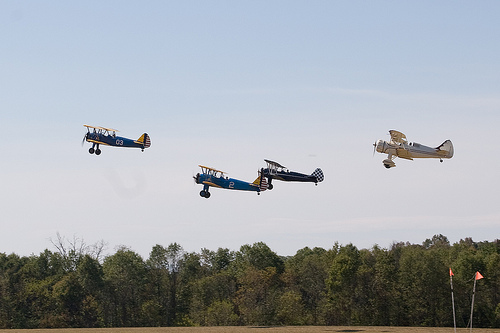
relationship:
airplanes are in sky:
[181, 154, 342, 214] [142, 30, 378, 126]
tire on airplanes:
[195, 187, 218, 203] [193, 164, 269, 198]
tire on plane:
[361, 154, 402, 171] [351, 123, 461, 185]